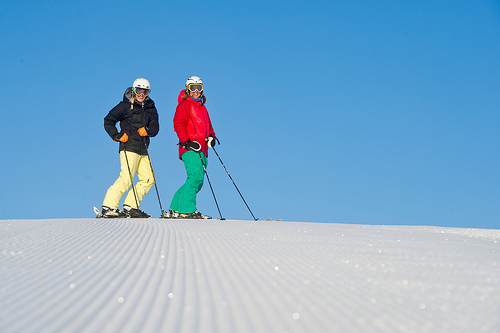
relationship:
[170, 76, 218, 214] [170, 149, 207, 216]
person with green pants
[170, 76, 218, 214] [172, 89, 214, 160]
person with red jacket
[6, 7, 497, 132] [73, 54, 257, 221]
sky behind skiers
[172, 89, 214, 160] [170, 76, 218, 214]
red jacket on person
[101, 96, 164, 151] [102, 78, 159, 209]
black jacket on person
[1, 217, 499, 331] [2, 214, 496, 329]
snow on slope